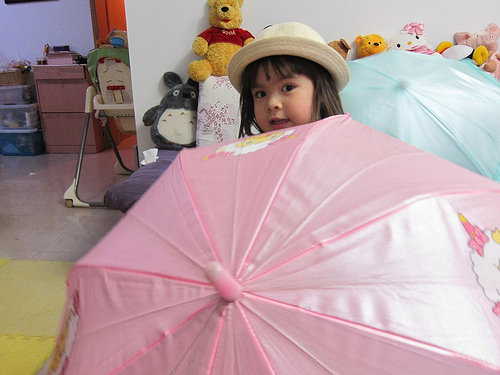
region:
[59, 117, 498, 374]
pink umbrella in foreground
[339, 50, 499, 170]
blue umbrella behind girl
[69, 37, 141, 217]
back of highchair seen on left in background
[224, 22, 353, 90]
little girl's cream colored hat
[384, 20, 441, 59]
Hello Kitty against wall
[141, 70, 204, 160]
strange-looking gray and white stuffed bunny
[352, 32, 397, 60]
Winnie the Pooh's head behind blue umbrella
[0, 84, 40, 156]
three stacked clear storage containers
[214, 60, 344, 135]
little girl's face and hair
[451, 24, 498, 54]
pig stuffed animal in top right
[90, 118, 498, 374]
girl with pink unbrella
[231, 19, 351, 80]
white hat on head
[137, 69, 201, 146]
gray and white stuffed animal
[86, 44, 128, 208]
high chair in room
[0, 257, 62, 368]
rug is yellow and gold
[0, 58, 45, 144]
toy boxes inthe room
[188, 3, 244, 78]
winnie the pooh teddy bear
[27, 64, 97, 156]
dresser in the corner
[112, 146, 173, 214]
dark covering for bed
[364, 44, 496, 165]
blue umbrella in background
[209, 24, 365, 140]
girl wearing beige hat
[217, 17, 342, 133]
girl with a short hair cut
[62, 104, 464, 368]
big pink umbrella with sheep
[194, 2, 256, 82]
winnie the pooh stuffed animal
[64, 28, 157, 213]
high chair with green seat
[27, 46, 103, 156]
small pink nightstand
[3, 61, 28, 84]
small wicker basket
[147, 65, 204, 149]
big gray and white stuffed animal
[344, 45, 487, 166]
big blue umbrella opened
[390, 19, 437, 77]
hello kitty stuffed animal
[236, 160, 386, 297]
the umbrella is pink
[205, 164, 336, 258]
the umbrella is pink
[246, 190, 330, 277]
the umbrella is pink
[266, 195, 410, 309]
the umbrella is pink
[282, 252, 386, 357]
the umbrella is pink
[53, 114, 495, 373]
opened pink umbrella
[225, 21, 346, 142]
head of a little girl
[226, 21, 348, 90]
white hat on little girls head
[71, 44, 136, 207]
high chair in the back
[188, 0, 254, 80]
large winnie the pooh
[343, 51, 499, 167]
the opened blue umbrella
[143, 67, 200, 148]
the large stuffed tortorro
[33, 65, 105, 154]
the cardboard box in the back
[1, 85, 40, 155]
the stack of clear plastic containers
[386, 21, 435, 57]
the stuffed hello kitty